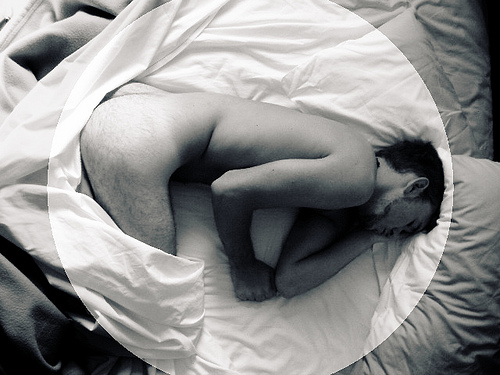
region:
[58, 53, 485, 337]
This is a dead person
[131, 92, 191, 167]
a tan line from the sun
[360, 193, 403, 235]
man has a beard along the jaw bone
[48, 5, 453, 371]
white circle drawn around a man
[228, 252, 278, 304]
right hand clenched in a fist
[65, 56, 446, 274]
sleeping in the fetal position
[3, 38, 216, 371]
sheets are pushed down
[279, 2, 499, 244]
two pillows are overlapped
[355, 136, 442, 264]
head resting in man's hand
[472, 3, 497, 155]
edge of the bed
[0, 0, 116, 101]
blanket pushed to the corner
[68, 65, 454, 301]
A man in the foreground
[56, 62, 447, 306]
The man is fully naked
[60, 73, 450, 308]
Man is naked in bed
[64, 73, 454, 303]
Man is laying on his side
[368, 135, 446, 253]
Man has dark colored hair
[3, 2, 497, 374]
Photo is in black and white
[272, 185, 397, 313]
Man's hand is under his head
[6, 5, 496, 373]
Photo was taken indoors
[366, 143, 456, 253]
A side view of a man's head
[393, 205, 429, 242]
Man's eyes are closed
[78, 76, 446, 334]
a naked man in bed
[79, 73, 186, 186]
the butt of a man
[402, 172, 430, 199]
the ear of a man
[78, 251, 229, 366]
a white sheet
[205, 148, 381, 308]
a man's arms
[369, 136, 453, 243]
the head of a man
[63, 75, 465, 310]
a naked man sleeping in a bed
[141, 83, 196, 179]
the tan line on a man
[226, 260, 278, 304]
a man has a balled up fist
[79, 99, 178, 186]
a man with a hairy butt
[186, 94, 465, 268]
man laying on bed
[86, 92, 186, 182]
naked butt on man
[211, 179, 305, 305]
right arm on man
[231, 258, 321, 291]
right hand on man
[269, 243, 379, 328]
left arm on man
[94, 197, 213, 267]
right leg on man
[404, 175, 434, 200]
right ear on man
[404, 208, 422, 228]
right eye on man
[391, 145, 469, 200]
dark hair on man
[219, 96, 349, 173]
tan back on man